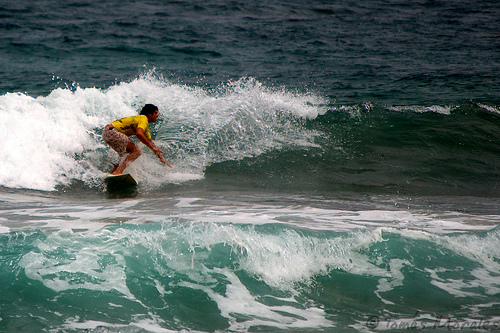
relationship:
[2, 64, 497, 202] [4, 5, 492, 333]
wave on water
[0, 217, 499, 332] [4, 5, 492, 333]
wave on water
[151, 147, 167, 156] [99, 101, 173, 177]
hand of swimmer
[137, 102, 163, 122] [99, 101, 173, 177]
head of swimmer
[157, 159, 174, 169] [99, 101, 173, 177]
hand of swimmer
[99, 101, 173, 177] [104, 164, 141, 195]
man on surfboard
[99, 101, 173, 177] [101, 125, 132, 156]
man wearing shorts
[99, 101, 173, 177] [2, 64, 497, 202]
surfer riding wave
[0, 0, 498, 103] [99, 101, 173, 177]
ocean behind surfer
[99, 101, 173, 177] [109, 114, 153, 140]
man in shirt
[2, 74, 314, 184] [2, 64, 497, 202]
foam on wave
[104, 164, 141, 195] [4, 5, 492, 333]
surfboard on water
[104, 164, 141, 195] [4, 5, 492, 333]
surfboard floating on water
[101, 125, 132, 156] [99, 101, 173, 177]
swim trunks on surfer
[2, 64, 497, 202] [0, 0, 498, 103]
wave on ocean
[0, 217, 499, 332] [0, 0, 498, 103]
wave on ocean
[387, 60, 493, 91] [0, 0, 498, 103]
wave on ocean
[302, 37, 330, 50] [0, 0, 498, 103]
wave on ocean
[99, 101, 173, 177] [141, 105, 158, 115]
man has hair